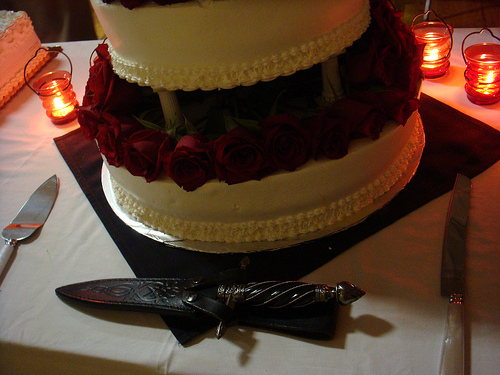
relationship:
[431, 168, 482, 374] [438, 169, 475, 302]
pie cutter has blade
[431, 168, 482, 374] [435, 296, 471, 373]
pie cutter has handle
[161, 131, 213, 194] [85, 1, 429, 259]
rose on cake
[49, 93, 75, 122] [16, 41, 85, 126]
candle inside of lamp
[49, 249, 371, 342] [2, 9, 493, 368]
dagger on top of table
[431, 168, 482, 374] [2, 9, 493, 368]
cake knife on top of table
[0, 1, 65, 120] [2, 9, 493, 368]
cake on top of table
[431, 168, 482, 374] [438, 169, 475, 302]
pie cutter has a blade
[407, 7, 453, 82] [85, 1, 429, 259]
candle behind cake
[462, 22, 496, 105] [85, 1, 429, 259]
candle behind cake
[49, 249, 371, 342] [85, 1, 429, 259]
knife in front of cake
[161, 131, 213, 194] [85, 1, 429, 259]
rose around cake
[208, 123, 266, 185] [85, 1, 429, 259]
rose around cake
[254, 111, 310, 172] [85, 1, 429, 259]
rose around cake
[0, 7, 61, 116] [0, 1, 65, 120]
edge of cake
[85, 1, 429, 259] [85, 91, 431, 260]
cake has bottom layer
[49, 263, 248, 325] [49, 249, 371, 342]
sheath covering knife blade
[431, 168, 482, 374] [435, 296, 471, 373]
knife has handle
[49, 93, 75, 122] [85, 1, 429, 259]
candle to left of cake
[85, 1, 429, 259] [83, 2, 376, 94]
cake has top layer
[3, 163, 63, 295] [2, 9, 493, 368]
serving knife on top of table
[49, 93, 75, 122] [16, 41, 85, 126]
tea light in jar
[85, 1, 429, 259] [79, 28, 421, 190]
cake with roses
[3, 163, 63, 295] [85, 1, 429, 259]
spatula serving cake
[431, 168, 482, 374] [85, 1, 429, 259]
knife for serving cake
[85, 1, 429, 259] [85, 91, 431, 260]
cake has tier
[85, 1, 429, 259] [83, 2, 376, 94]
cake has tier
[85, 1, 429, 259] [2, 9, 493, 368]
wedding cake on top of table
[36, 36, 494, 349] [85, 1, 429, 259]
napkin under cake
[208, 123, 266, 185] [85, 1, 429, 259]
rose on cake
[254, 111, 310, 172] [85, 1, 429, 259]
rose on cake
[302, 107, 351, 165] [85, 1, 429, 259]
rose on cake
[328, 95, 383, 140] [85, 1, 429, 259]
rose on cake